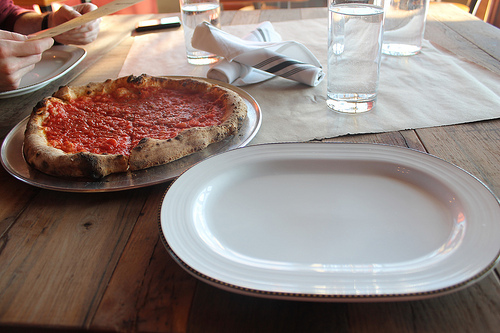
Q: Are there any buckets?
A: No, there are no buckets.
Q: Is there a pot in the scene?
A: No, there are no pots.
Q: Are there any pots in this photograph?
A: No, there are no pots.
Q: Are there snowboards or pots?
A: No, there are no pots or snowboards.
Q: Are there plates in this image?
A: Yes, there is a plate.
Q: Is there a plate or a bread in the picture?
A: Yes, there is a plate.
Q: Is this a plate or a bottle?
A: This is a plate.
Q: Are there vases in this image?
A: No, there are no vases.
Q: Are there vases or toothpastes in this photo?
A: No, there are no vases or toothpastes.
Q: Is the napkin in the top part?
A: Yes, the napkin is in the top of the image.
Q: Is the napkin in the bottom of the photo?
A: No, the napkin is in the top of the image.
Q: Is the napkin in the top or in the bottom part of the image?
A: The napkin is in the top of the image.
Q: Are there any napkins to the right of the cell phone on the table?
A: Yes, there is a napkin to the right of the mobile phone.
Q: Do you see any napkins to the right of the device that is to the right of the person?
A: Yes, there is a napkin to the right of the mobile phone.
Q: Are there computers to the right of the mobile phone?
A: No, there is a napkin to the right of the mobile phone.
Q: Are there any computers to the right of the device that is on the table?
A: No, there is a napkin to the right of the mobile phone.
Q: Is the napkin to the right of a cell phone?
A: Yes, the napkin is to the right of a cell phone.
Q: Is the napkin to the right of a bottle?
A: No, the napkin is to the right of a cell phone.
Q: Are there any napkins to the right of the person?
A: Yes, there is a napkin to the right of the person.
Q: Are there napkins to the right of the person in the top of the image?
A: Yes, there is a napkin to the right of the person.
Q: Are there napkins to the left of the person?
A: No, the napkin is to the right of the person.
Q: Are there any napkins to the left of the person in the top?
A: No, the napkin is to the right of the person.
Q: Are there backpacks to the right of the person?
A: No, there is a napkin to the right of the person.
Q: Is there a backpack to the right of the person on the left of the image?
A: No, there is a napkin to the right of the person.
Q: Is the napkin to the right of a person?
A: Yes, the napkin is to the right of a person.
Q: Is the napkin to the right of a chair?
A: No, the napkin is to the right of a person.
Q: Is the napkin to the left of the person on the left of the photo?
A: No, the napkin is to the right of the person.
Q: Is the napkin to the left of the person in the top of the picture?
A: No, the napkin is to the right of the person.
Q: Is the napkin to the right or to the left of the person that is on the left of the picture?
A: The napkin is to the right of the person.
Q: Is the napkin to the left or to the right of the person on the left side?
A: The napkin is to the right of the person.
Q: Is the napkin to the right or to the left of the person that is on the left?
A: The napkin is to the right of the person.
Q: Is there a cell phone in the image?
A: Yes, there is a cell phone.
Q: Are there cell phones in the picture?
A: Yes, there is a cell phone.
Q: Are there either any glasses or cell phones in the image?
A: Yes, there is a cell phone.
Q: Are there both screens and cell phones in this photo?
A: No, there is a cell phone but no screens.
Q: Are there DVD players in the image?
A: No, there are no DVD players.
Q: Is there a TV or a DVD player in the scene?
A: No, there are no DVD players or televisions.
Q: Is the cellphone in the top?
A: Yes, the cellphone is in the top of the image.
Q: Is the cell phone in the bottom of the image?
A: No, the cell phone is in the top of the image.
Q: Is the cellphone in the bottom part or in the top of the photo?
A: The cellphone is in the top of the image.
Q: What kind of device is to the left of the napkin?
A: The device is a cell phone.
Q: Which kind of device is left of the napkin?
A: The device is a cell phone.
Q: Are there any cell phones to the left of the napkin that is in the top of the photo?
A: Yes, there is a cell phone to the left of the napkin.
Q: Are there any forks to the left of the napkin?
A: No, there is a cell phone to the left of the napkin.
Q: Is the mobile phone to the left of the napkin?
A: Yes, the mobile phone is to the left of the napkin.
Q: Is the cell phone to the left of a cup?
A: No, the cell phone is to the left of the napkin.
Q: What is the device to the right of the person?
A: The device is a cell phone.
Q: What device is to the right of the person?
A: The device is a cell phone.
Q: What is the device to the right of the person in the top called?
A: The device is a cell phone.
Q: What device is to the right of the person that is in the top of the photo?
A: The device is a cell phone.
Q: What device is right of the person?
A: The device is a cell phone.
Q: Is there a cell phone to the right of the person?
A: Yes, there is a cell phone to the right of the person.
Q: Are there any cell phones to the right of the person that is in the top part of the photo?
A: Yes, there is a cell phone to the right of the person.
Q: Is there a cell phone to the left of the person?
A: No, the cell phone is to the right of the person.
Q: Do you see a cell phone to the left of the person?
A: No, the cell phone is to the right of the person.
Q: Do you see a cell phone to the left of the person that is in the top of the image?
A: No, the cell phone is to the right of the person.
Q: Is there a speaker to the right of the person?
A: No, there is a cell phone to the right of the person.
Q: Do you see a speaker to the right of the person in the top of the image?
A: No, there is a cell phone to the right of the person.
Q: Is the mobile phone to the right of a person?
A: Yes, the mobile phone is to the right of a person.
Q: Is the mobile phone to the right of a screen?
A: No, the mobile phone is to the right of a person.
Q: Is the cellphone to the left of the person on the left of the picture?
A: No, the cellphone is to the right of the person.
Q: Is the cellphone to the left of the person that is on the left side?
A: No, the cellphone is to the right of the person.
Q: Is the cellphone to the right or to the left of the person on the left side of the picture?
A: The cellphone is to the right of the person.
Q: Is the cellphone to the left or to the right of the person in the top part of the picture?
A: The cellphone is to the right of the person.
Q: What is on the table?
A: The cell phone is on the table.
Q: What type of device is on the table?
A: The device is a cell phone.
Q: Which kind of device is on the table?
A: The device is a cell phone.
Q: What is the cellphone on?
A: The cellphone is on the table.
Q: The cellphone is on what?
A: The cellphone is on the table.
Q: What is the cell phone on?
A: The cellphone is on the table.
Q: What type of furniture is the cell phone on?
A: The cell phone is on the table.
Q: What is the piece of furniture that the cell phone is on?
A: The piece of furniture is a table.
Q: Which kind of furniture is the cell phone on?
A: The cell phone is on the table.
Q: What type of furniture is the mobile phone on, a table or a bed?
A: The mobile phone is on a table.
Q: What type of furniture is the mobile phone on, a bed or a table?
A: The mobile phone is on a table.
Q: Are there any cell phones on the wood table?
A: Yes, there is a cell phone on the table.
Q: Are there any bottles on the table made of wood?
A: No, there is a cell phone on the table.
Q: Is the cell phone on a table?
A: Yes, the cell phone is on a table.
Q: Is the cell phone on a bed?
A: No, the cell phone is on a table.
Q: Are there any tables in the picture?
A: Yes, there is a table.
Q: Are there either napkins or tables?
A: Yes, there is a table.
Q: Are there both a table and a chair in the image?
A: No, there is a table but no chairs.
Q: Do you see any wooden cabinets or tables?
A: Yes, there is a wood table.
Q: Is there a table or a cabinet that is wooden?
A: Yes, the table is wooden.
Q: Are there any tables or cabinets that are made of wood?
A: Yes, the table is made of wood.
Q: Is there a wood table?
A: Yes, there is a table that is made of wood.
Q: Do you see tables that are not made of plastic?
A: Yes, there is a table that is made of wood.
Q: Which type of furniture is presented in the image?
A: The furniture is a table.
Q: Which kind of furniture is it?
A: The piece of furniture is a table.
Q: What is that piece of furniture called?
A: This is a table.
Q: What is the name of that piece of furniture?
A: This is a table.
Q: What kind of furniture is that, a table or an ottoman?
A: This is a table.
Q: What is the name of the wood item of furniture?
A: The piece of furniture is a table.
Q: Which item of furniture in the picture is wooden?
A: The piece of furniture is a table.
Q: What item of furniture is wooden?
A: The piece of furniture is a table.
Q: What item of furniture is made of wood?
A: The piece of furniture is a table.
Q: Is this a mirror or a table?
A: This is a table.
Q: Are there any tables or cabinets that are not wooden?
A: No, there is a table but it is wooden.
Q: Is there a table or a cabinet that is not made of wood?
A: No, there is a table but it is made of wood.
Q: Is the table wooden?
A: Yes, the table is wooden.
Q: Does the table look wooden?
A: Yes, the table is wooden.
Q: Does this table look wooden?
A: Yes, the table is wooden.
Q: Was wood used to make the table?
A: Yes, the table is made of wood.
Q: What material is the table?
A: The table is made of wood.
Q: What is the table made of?
A: The table is made of wood.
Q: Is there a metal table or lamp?
A: No, there is a table but it is wooden.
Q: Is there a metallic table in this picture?
A: No, there is a table but it is wooden.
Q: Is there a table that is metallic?
A: No, there is a table but it is wooden.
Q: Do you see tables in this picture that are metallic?
A: No, there is a table but it is wooden.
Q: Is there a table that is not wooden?
A: No, there is a table but it is wooden.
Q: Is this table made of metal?
A: No, the table is made of wood.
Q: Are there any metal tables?
A: No, there is a table but it is made of wood.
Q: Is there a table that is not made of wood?
A: No, there is a table but it is made of wood.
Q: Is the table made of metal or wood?
A: The table is made of wood.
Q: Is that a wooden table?
A: Yes, that is a wooden table.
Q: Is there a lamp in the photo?
A: No, there are no lamps.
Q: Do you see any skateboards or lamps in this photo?
A: No, there are no lamps or skateboards.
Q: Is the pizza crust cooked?
A: Yes, the pizza crust is cooked.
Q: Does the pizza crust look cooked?
A: Yes, the pizza crust is cooked.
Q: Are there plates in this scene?
A: Yes, there is a plate.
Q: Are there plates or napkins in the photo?
A: Yes, there is a plate.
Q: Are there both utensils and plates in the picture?
A: No, there is a plate but no utensils.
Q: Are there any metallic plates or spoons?
A: Yes, there is a metal plate.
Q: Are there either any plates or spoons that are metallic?
A: Yes, the plate is metallic.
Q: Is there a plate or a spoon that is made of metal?
A: Yes, the plate is made of metal.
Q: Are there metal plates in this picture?
A: Yes, there is a metal plate.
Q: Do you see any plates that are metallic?
A: Yes, there is a metal plate.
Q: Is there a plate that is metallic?
A: Yes, there is a plate that is metallic.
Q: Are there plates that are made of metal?
A: Yes, there is a plate that is made of metal.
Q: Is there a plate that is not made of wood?
A: Yes, there is a plate that is made of metal.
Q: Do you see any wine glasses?
A: No, there are no wine glasses.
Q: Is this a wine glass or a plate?
A: This is a plate.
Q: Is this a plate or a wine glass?
A: This is a plate.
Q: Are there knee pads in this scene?
A: No, there are no knee pads.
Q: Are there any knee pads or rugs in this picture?
A: No, there are no knee pads or rugs.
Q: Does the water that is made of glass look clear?
A: Yes, the water is clear.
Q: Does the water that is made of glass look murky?
A: No, the water is clear.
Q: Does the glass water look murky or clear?
A: The water is clear.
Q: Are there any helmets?
A: No, there are no helmets.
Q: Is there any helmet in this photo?
A: No, there are no helmets.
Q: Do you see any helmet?
A: No, there are no helmets.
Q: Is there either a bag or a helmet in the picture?
A: No, there are no helmets or bags.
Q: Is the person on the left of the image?
A: Yes, the person is on the left of the image.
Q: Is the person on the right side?
A: No, the person is on the left of the image.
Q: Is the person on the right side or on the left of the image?
A: The person is on the left of the image.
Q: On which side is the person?
A: The person is on the left of the image.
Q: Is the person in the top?
A: Yes, the person is in the top of the image.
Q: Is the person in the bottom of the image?
A: No, the person is in the top of the image.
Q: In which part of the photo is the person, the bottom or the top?
A: The person is in the top of the image.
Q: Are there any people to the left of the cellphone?
A: Yes, there is a person to the left of the cellphone.